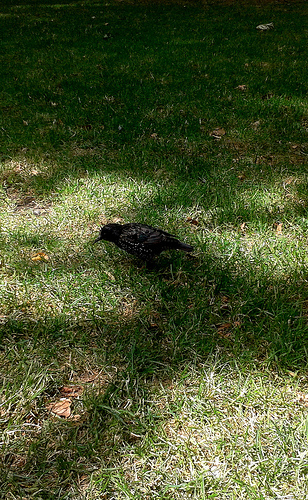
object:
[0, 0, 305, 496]
grass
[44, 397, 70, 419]
leaf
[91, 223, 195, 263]
bird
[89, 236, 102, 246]
beak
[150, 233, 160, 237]
feathers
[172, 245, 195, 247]
feathers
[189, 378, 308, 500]
sunlight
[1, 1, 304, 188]
shadow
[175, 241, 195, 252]
tail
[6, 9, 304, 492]
scene